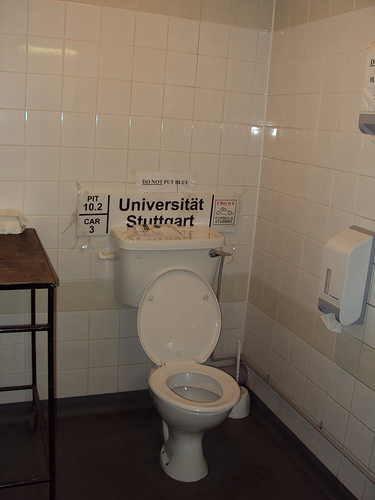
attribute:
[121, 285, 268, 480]
toilet — white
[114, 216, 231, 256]
sink — white, open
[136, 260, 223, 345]
lid — white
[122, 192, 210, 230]
writing — black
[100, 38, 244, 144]
wall — tile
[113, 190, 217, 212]
word — universitat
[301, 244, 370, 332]
tissue dispesor — white, mouted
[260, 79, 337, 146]
tiles — white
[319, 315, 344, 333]
tissue — white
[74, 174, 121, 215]
paper — taped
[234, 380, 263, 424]
bowl cleaner — white